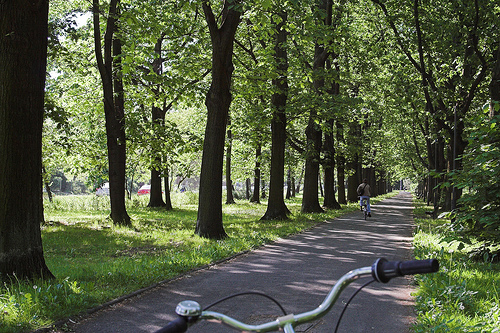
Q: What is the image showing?
A: It is showing a path.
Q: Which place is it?
A: It is a path.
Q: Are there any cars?
A: No, there are no cars.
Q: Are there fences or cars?
A: No, there are no cars or fences.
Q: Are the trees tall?
A: Yes, the trees are tall.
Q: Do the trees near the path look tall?
A: Yes, the trees are tall.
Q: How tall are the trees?
A: The trees are tall.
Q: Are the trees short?
A: No, the trees are tall.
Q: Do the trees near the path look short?
A: No, the trees are tall.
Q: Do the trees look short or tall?
A: The trees are tall.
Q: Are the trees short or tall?
A: The trees are tall.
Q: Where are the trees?
A: The trees are on the grass.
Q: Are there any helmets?
A: No, there are no helmets.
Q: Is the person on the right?
A: Yes, the person is on the right of the image.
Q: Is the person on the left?
A: No, the person is on the right of the image.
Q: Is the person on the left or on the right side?
A: The person is on the right of the image.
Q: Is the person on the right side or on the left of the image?
A: The person is on the right of the image.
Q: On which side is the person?
A: The person is on the right of the image.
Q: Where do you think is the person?
A: The person is on the path.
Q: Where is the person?
A: The person is on the path.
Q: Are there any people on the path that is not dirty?
A: Yes, there is a person on the path.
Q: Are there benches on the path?
A: No, there is a person on the path.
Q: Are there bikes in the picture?
A: Yes, there is a bike.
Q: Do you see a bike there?
A: Yes, there is a bike.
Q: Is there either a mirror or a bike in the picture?
A: Yes, there is a bike.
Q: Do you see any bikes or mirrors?
A: Yes, there is a bike.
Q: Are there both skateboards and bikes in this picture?
A: No, there is a bike but no skateboards.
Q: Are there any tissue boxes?
A: No, there are no tissue boxes.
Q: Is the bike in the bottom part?
A: Yes, the bike is in the bottom of the image.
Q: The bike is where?
A: The bike is on the path.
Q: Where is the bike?
A: The bike is on the path.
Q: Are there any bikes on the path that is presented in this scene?
A: Yes, there is a bike on the path.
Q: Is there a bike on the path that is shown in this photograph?
A: Yes, there is a bike on the path.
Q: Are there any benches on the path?
A: No, there is a bike on the path.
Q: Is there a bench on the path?
A: No, there is a bike on the path.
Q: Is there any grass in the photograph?
A: Yes, there is grass.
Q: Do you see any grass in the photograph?
A: Yes, there is grass.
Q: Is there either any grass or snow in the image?
A: Yes, there is grass.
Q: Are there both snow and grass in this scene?
A: No, there is grass but no snow.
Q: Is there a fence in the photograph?
A: No, there are no fences.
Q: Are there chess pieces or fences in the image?
A: No, there are no fences or chess pieces.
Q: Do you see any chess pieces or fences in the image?
A: No, there are no fences or chess pieces.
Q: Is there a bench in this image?
A: No, there are no benches.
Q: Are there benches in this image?
A: No, there are no benches.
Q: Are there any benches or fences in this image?
A: No, there are no benches or fences.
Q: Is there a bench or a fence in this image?
A: No, there are no benches or fences.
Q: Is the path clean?
A: Yes, the path is clean.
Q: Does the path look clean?
A: Yes, the path is clean.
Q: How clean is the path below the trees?
A: The path is clean.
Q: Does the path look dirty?
A: No, the path is clean.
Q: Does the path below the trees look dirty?
A: No, the path is clean.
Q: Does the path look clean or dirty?
A: The path is clean.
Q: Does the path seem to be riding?
A: Yes, the path is riding.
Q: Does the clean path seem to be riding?
A: Yes, the path is riding.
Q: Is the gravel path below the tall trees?
A: Yes, the path is below the trees.